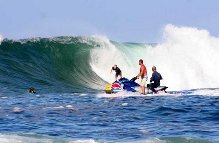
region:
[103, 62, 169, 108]
people jet skiing next to a large wave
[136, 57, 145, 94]
a man wearing yellow swimming trunks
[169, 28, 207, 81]
water spraying into the air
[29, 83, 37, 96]
a black object in the ocean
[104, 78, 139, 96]
a brightly colored jet ski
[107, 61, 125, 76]
a man wearing a black wet suit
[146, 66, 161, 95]
a person wearing a blue shirt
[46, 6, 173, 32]
a clear blue sky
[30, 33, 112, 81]
a hug waving rolling in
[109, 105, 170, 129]
choppy blue sea water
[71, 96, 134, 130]
green color in water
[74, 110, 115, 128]
rough blue waters in the ocean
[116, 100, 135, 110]
small white wave on the water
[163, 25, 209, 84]
large section of white waves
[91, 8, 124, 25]
clear blue skies over head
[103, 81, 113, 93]
yellow front of wave runner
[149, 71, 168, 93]
blue shiny wet suit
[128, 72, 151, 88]
man holding handle of wave runner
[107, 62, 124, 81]
man crouching on wave runner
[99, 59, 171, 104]
people standing on wave runners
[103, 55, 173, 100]
People in the ocean.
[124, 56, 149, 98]
Man on jet ski.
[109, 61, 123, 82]
Surfer riding wave.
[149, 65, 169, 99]
Man sitting on jet ski.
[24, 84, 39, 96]
Person in water.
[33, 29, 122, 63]
Large wave in the ocean.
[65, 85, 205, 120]
The water is choppy.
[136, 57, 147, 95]
Man is wearing shorts.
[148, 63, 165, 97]
Man on jet ski is wearing a wet suit.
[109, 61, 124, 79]
Surfer is wearing a black shirt.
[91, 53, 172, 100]
three people on jet skis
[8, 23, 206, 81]
large ocean wave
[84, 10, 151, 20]
bright clear blue sky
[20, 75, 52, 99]
person in ocean under wave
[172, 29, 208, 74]
white water created by crashing wave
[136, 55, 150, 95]
man standing on jet ski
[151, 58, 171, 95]
man sitting on back of jet ski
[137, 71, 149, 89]
white shorts worn by man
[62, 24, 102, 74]
wave of ocean looks green from light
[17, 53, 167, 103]
four people in the picture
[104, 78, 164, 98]
a red bull jet ski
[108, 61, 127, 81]
a man surfing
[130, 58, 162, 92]
two people on the jet ski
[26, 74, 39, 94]
a black object in the water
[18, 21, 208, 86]
a large wave crashing down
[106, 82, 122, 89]
the red bull logo on the jet ski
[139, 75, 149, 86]
white and yellow swim trunks on a man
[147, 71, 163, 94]
a black and blue wet suit on a man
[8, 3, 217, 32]
clear skies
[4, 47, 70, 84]
a wave about to crest